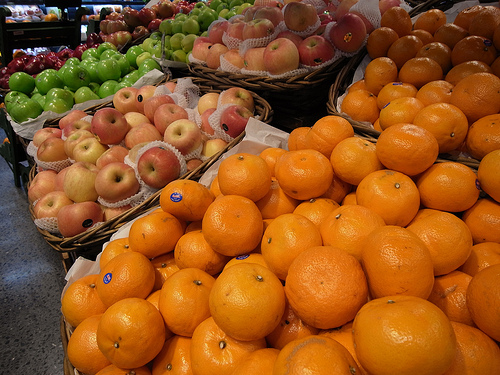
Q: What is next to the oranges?
A: Apples.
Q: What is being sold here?
A: Fruit.